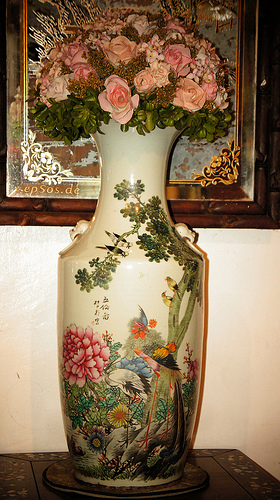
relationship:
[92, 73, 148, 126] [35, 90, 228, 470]
flower in vase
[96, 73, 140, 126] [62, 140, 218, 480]
flower on vase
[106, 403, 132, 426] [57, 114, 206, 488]
flower on vase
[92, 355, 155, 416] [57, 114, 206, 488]
bird painted on vase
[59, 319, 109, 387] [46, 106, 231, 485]
flower painted on vase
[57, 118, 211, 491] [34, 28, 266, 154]
vase with flower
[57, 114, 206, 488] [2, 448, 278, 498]
vase on table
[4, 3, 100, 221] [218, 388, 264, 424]
framed picture on wall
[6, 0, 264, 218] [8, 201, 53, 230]
frame on wall